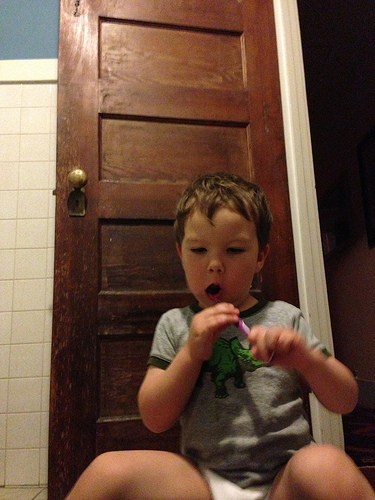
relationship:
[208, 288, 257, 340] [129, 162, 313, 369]
toothbrush in kid's mouth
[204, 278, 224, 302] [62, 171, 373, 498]
kid's mouth of kid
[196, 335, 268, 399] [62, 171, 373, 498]
dinosaur of kid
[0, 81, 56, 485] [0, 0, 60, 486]
tile on wall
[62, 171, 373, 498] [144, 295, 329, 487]
kid wearing shirt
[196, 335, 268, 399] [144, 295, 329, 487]
dinosaur on shirt